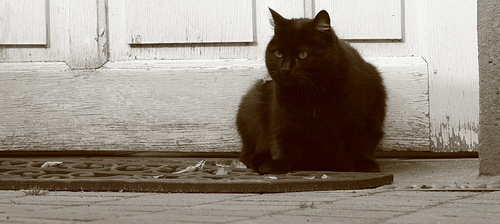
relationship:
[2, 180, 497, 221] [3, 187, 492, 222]
bricks on ground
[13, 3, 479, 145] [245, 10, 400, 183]
wood behind cat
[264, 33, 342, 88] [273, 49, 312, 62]
cat's face has eyes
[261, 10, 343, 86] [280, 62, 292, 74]
cat's face has nose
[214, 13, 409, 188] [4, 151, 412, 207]
black cat sitting on door mat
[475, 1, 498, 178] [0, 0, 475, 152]
wall next to door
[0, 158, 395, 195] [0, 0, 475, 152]
door mat by door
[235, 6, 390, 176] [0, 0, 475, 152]
black cat by door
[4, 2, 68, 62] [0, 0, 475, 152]
panels on door